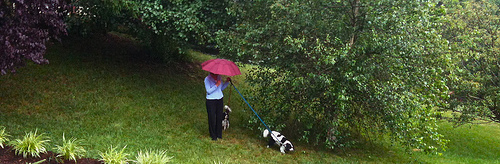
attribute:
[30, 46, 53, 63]
leaves — purple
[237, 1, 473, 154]
tree — large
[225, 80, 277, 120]
leash — blue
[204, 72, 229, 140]
woman — red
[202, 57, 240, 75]
umbrella — open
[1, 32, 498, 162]
grass — large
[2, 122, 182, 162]
plants row — spiky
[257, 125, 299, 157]
dog — white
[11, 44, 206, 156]
grass — green 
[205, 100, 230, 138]
pants — black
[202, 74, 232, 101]
shirt — blue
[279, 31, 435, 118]
leaves — purple 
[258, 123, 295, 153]
dog — black and white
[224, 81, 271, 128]
leash — blue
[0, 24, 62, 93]
flowers — purple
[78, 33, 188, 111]
shade — deep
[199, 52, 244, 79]
umbrella — pink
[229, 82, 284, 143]
leash — blue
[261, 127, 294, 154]
dog — walking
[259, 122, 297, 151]
dog — black, white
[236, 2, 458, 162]
tree — large, green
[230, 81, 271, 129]
leash — blue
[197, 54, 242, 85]
umbrella — pink